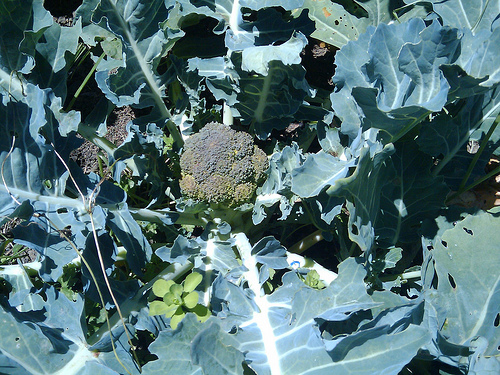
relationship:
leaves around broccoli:
[310, 7, 484, 351] [159, 121, 299, 235]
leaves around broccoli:
[0, 0, 498, 374] [166, 119, 279, 213]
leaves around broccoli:
[0, 280, 117, 373] [182, 120, 264, 190]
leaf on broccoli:
[287, 135, 395, 201] [177, 120, 272, 205]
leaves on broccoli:
[0, 0, 498, 374] [177, 120, 272, 205]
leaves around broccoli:
[332, 150, 385, 270] [177, 120, 272, 205]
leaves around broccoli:
[353, 17, 453, 136] [177, 120, 272, 205]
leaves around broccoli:
[216, 229, 424, 374] [177, 120, 272, 205]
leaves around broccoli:
[93, 4, 180, 104] [177, 120, 272, 205]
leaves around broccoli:
[234, 40, 307, 135] [177, 120, 272, 205]